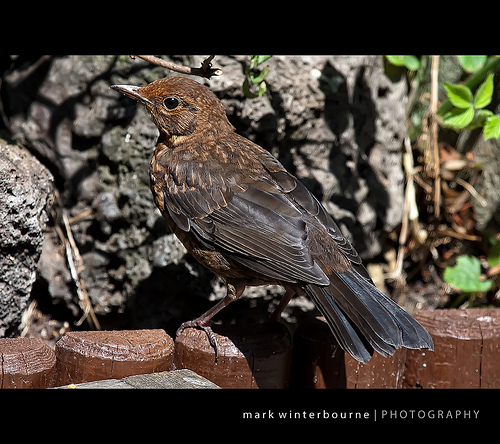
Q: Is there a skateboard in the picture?
A: No, there are no skateboards.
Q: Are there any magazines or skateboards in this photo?
A: No, there are no skateboards or magazines.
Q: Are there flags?
A: No, there are no flags.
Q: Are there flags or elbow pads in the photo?
A: No, there are no flags or elbow pads.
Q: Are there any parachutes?
A: No, there are no parachutes.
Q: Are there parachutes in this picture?
A: No, there are no parachutes.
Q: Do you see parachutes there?
A: No, there are no parachutes.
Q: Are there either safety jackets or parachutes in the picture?
A: No, there are no parachutes or safety jackets.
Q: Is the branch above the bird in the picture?
A: Yes, the branch is above the bird.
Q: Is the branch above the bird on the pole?
A: Yes, the branch is above the bird.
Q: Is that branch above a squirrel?
A: No, the branch is above the bird.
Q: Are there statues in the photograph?
A: No, there are no statues.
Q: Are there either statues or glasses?
A: No, there are no statues or glasses.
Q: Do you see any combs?
A: No, there are no combs.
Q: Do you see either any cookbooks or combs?
A: No, there are no combs or cookbooks.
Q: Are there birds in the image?
A: Yes, there is a bird.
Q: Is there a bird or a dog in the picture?
A: Yes, there is a bird.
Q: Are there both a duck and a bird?
A: No, there is a bird but no ducks.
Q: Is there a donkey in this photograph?
A: No, there are no donkeys.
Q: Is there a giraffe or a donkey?
A: No, there are no donkeys or giraffes.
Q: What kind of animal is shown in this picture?
A: The animal is a bird.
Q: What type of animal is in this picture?
A: The animal is a bird.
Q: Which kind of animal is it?
A: The animal is a bird.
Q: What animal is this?
A: This is a bird.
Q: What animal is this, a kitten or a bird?
A: This is a bird.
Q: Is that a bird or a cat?
A: That is a bird.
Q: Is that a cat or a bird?
A: That is a bird.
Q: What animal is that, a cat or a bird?
A: That is a bird.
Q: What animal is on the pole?
A: The bird is on the pole.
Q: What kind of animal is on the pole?
A: The animal is a bird.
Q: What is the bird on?
A: The bird is on the pole.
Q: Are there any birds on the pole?
A: Yes, there is a bird on the pole.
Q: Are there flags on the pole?
A: No, there is a bird on the pole.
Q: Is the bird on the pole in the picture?
A: Yes, the bird is on the pole.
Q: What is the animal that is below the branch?
A: The animal is a bird.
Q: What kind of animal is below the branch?
A: The animal is a bird.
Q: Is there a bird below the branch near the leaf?
A: Yes, there is a bird below the branch.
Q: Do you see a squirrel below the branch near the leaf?
A: No, there is a bird below the branch.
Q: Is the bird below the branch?
A: Yes, the bird is below the branch.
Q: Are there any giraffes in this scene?
A: No, there are no giraffes.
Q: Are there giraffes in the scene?
A: No, there are no giraffes.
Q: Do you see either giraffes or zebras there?
A: No, there are no giraffes or zebras.